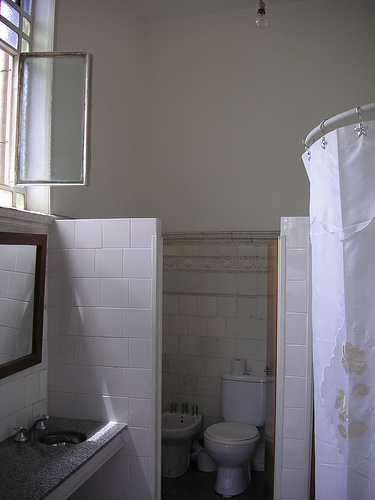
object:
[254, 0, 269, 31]
light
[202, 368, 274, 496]
toilet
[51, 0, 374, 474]
wall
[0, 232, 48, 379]
mirror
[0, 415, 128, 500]
sink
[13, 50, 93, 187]
window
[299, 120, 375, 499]
curtains